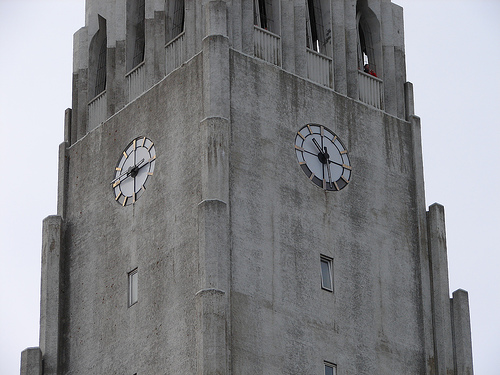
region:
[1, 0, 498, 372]
Grey clock tower against a grey sky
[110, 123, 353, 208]
Two clocks on a clock tower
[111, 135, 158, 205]
A clock reading 2:45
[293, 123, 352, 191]
A clock reading 10:27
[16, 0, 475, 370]
Grey concrete tower stained by rain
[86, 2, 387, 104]
Cut-out windows on top of tower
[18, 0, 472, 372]
Large concrete building on a cloudy day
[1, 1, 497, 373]
Cloudy blue-grey sky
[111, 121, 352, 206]
Two mostly white clocks blackened between 4 and 8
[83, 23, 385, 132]
Guard rails by windows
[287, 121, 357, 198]
clock face on a large grey building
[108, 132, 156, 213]
clock face on a large grey building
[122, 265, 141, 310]
rectangular window on a grey building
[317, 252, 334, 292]
rectangular window on a grey building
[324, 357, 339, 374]
rectangular window on a grey building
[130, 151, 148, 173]
black metal hand on the clock face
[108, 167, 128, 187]
black metal hand on the clock face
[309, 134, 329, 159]
black metal hand on the clock face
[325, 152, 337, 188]
black metal hand on the clock face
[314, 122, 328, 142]
number marker on a clock face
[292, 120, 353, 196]
modern clock face on a grey tower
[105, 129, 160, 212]
modern clock face on a grey tower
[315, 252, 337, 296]
small window on a grey tower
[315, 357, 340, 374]
small window on a grey tower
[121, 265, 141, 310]
small window on a grey tower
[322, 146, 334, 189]
metal hand on a clock face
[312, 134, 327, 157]
metal hand on a clock face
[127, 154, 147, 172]
metal hand on a clock face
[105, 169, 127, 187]
metal hand on a clock face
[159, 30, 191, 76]
concrete railing on a balcony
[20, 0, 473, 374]
the large clock tower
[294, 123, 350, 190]
the clock on the tower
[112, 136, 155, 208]
the clock on the tower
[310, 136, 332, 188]
the hands on the clock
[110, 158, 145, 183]
the hands on the clock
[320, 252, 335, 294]
the window on the tower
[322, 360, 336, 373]
the window on the tower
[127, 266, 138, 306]
the window on the tower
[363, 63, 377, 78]
the person on the tower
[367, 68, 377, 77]
the red object on the tower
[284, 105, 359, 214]
round clock embedded in building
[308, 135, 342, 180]
hands of analog clock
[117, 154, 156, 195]
hands of analog clock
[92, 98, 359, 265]
two grey analog clocks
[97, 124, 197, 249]
grey analog clock in building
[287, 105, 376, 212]
grey analog clock in building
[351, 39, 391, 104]
person at top of building